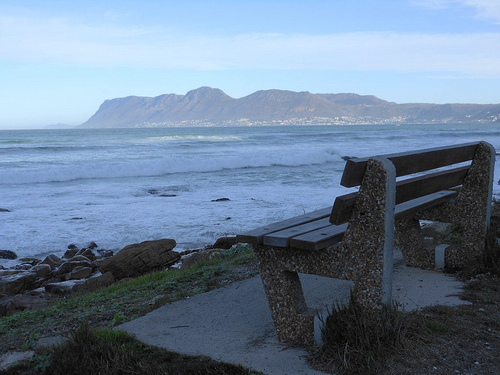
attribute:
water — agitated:
[2, 142, 334, 193]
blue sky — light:
[21, 2, 474, 86]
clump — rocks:
[0, 225, 189, 292]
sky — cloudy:
[22, 12, 477, 94]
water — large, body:
[0, 120, 498, 255]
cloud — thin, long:
[189, 30, 384, 66]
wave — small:
[137, 128, 249, 148]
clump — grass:
[181, 235, 218, 270]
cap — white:
[146, 134, 240, 144]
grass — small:
[107, 281, 137, 313]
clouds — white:
[1, 11, 482, 84]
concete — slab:
[111, 231, 482, 372]